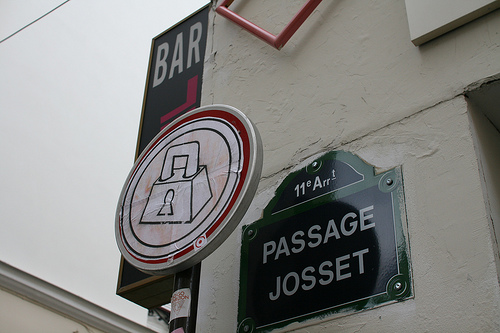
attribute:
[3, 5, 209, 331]
cloud — white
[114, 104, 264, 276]
sign — red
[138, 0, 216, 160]
sign — black, white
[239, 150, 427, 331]
sign — black, green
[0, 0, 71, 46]
wire — above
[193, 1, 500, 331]
building — white